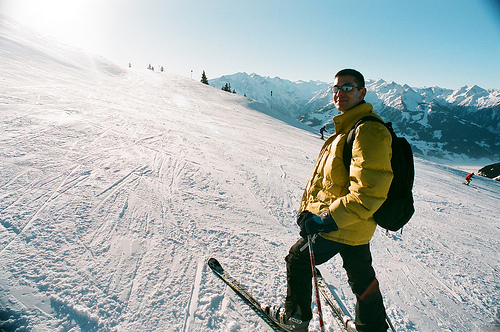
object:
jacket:
[297, 101, 397, 248]